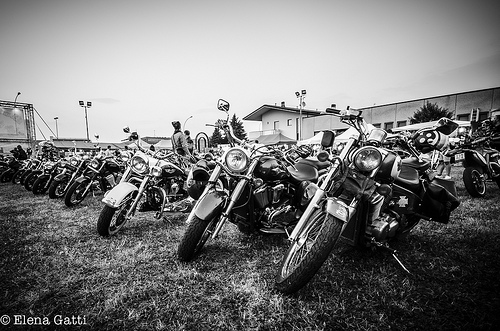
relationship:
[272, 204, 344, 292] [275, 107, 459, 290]
wheel on motorcycle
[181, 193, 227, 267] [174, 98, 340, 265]
wheel on motorcycle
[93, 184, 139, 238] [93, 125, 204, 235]
wheel on motorcycle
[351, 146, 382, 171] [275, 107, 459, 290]
light on motorcycle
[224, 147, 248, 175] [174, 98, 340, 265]
light on motorcycle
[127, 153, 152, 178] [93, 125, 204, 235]
light on motorcycle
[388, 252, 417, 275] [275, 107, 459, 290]
kickstand on motorcycle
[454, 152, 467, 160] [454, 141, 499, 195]
plate on motorcycle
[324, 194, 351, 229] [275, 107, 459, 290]
fender on motorcycle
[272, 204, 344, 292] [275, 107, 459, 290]
tire on motorcycle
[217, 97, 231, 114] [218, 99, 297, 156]
mirror on handlebar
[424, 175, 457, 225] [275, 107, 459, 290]
bags on motorcycle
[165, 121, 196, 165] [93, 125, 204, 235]
people by motorcycle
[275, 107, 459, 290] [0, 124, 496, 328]
motorcycle in grass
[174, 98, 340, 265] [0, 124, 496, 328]
motorcycle in grass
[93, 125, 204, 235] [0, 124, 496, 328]
motorcycle in grass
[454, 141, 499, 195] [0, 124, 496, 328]
motorcycle in grass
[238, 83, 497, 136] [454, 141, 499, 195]
building behind motorcycle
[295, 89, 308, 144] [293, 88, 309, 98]
post with lights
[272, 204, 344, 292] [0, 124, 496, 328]
wheel in grass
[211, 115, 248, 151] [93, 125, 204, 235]
tree behind motorcycle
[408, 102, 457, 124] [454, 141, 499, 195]
tree behind motorcycle